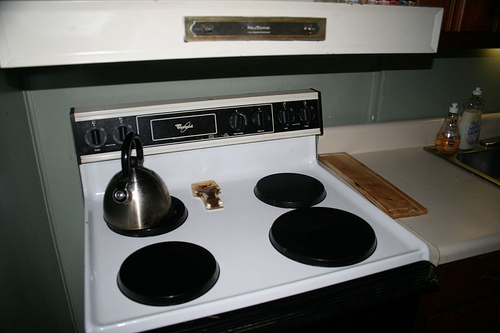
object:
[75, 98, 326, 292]
stove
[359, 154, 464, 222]
counter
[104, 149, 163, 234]
kettle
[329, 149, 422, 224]
board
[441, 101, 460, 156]
bottle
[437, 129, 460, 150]
soap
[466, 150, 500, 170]
sink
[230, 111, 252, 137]
knob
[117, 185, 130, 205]
spout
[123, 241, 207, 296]
burner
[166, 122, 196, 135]
logo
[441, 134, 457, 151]
bubbles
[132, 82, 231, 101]
wall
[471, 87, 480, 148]
bottle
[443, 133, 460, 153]
oil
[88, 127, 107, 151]
dial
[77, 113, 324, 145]
control panel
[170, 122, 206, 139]
name brand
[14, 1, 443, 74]
ventilation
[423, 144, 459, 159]
tray